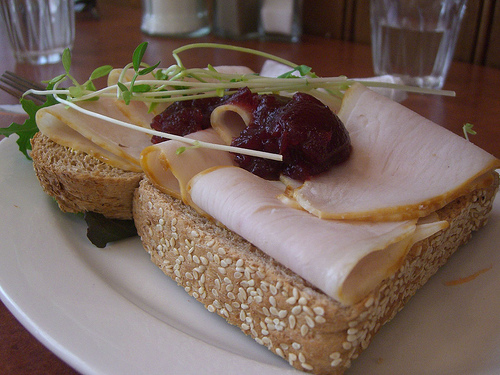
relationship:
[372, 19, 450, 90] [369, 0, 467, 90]
water in container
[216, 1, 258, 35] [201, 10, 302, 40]
pepper in container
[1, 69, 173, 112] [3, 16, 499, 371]
fork on table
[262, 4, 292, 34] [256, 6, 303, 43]
salt in container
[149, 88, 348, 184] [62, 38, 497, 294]
sauce on meat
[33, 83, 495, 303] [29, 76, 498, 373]
white meat on bread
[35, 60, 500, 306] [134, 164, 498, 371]
lunch meat on bread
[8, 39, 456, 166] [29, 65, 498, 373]
garnish on bread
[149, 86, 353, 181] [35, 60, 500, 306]
sauce on lunch meat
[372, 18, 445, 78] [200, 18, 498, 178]
water on table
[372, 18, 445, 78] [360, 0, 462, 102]
water in glass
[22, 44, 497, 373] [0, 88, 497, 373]
food on plate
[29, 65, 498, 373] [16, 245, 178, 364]
bread on plate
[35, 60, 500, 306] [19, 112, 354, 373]
lunch meat on bread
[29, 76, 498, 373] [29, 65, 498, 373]
bread of bread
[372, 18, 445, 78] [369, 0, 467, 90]
water in container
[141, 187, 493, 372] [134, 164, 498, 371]
seeds on bread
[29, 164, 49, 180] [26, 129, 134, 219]
seeds on bread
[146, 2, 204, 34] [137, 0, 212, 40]
sugar in container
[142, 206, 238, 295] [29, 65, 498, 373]
sesame seeds on bread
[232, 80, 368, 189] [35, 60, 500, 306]
berry preserves on lunch meat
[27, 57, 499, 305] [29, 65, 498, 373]
lunch meat on bread